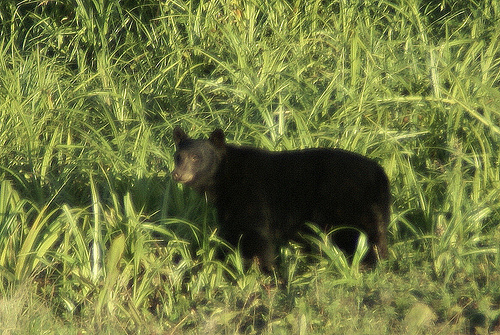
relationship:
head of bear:
[168, 122, 227, 186] [169, 125, 396, 275]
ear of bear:
[208, 128, 226, 143] [169, 125, 396, 275]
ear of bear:
[170, 126, 188, 141] [169, 125, 396, 275]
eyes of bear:
[174, 152, 200, 164] [169, 125, 396, 275]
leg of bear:
[252, 235, 284, 273] [169, 125, 396, 275]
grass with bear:
[1, 2, 499, 334] [169, 125, 396, 275]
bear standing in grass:
[169, 125, 396, 275] [1, 2, 499, 334]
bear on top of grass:
[169, 125, 396, 275] [1, 2, 499, 334]